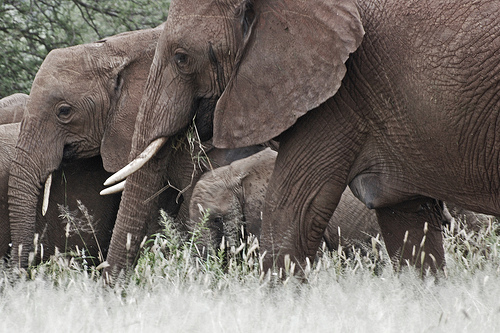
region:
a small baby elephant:
[176, 137, 439, 288]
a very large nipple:
[356, 193, 385, 217]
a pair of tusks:
[92, 129, 174, 214]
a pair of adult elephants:
[16, 1, 476, 266]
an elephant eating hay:
[91, 0, 462, 302]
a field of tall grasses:
[28, 200, 485, 324]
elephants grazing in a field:
[16, 12, 466, 312]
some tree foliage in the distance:
[12, 0, 138, 64]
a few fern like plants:
[346, 231, 405, 276]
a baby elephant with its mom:
[11, 22, 383, 297]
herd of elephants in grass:
[27, 19, 432, 304]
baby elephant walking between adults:
[180, 168, 325, 293]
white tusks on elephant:
[86, 121, 182, 228]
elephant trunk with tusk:
[10, 106, 86, 287]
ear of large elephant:
[213, 2, 364, 149]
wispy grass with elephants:
[156, 206, 229, 268]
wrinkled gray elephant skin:
[393, 32, 495, 155]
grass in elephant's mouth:
[150, 90, 224, 173]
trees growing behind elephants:
[7, 8, 79, 44]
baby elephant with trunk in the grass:
[187, 186, 257, 288]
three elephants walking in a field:
[24, 7, 482, 296]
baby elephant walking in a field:
[180, 153, 390, 268]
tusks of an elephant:
[91, 130, 191, 206]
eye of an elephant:
[152, 33, 204, 75]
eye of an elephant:
[51, 92, 80, 126]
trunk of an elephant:
[7, 114, 62, 291]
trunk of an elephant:
[110, 77, 193, 279]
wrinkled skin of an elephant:
[370, 14, 485, 175]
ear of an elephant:
[211, 1, 393, 156]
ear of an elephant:
[97, 51, 151, 167]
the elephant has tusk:
[14, 54, 227, 221]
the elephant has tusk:
[50, 57, 342, 311]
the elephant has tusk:
[45, 46, 250, 263]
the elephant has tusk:
[41, 39, 323, 312]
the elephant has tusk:
[71, 28, 264, 310]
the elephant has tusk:
[65, 38, 285, 300]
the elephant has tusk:
[58, 29, 274, 330]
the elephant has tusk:
[80, 44, 270, 315]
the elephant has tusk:
[108, 88, 238, 310]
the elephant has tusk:
[52, 58, 299, 325]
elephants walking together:
[12, 3, 467, 245]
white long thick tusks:
[78, 122, 180, 202]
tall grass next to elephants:
[20, 216, 357, 318]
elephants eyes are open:
[145, 27, 205, 67]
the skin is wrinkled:
[326, 32, 492, 123]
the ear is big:
[192, 0, 364, 170]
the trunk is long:
[100, 75, 175, 290]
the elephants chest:
[320, 135, 412, 225]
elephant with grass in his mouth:
[106, 97, 216, 177]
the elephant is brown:
[80, 10, 372, 140]